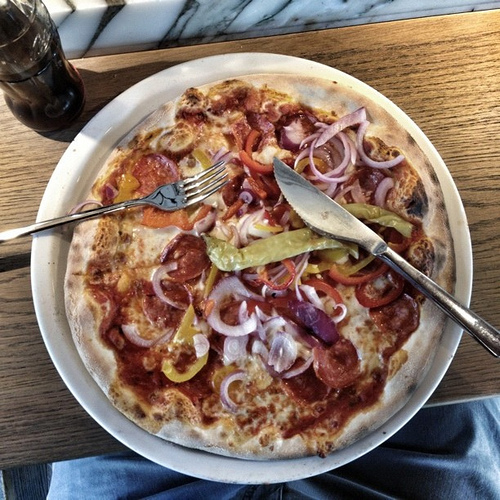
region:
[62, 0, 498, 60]
black and white marble countertop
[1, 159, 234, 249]
bright silver metal fork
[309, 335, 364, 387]
round red and white piece of pepperoni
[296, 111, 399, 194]
group of red onion pieces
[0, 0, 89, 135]
glass soda bottle with dark brown liquid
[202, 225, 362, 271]
large wrinkled green pepper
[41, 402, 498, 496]
small section of a lap wearing blue jeans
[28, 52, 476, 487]
round white pan holding pizza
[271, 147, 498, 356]
silver metal knife with serrated edge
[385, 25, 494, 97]
section of light brown tabletop with dark stripes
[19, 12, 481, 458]
a plate of food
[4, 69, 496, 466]
a plateof pizza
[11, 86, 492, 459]
a small pizza on a plate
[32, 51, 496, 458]
a personal size pizza on a plate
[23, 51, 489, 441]
an uncut pizza on a plate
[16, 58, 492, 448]
plate of pizza on the table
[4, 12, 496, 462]
a plate of pizza on a brown table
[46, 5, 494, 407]
pizza with onions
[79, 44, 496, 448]
cooked pizza with onions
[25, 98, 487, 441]
pizza with red sauce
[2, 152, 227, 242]
a stainless steel fork on a plate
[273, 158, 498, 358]
a stainless steel knife on a plate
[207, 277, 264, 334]
a slice of purple onion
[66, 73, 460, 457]
a thin pizza on a plate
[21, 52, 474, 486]
a white plate on a wooden table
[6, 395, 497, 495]
a blue cloth napkin on a table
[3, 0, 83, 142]
a glass bottle of soda on a table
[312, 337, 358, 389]
a slice of pepperoni on a pizza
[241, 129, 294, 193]
red peppers on a pizza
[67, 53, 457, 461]
a pepperoni pizza with veggies and cheese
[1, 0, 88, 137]
Coke in a classic glass bottle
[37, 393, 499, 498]
our diner is wearing blue pants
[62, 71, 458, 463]
the meal consists of a personal sized pizza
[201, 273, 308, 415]
there are red onions on this pizza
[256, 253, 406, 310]
there are red peppers on this pizza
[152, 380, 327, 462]
the cheese is browned on this pizza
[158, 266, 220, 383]
there are yellow peppers on this pizza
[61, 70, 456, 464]
someone is eating vegetarian pizza for lunch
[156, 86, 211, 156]
there are mushrooms on this pizza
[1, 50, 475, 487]
our diner is planning to eat pizza with a knife and fork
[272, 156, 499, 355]
the knife on the plate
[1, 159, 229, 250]
the fork on the plate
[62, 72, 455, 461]
the food on the plate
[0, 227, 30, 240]
the reflection on the fork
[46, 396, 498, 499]
the denim jeans under the table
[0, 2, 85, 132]
the soda bottle near the plate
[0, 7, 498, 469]
the wood piece under the plate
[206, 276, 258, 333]
the onion slice on the pizza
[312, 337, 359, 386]
the pepperoni slice on the pizza